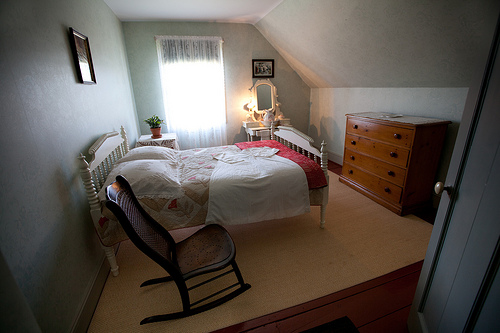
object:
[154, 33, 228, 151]
curtains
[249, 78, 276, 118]
mirror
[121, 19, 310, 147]
wall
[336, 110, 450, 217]
dresser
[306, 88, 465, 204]
wall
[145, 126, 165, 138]
flower pot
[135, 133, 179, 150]
table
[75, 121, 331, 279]
bed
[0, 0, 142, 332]
wall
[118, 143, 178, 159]
pillow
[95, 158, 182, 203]
pillow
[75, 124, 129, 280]
headboard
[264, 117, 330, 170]
footboard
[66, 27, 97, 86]
picture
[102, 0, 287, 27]
ceiling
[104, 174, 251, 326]
rocker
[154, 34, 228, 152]
window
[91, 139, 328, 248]
quilt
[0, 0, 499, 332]
bedroom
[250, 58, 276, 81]
picture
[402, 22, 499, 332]
door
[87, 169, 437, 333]
carpet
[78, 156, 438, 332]
floor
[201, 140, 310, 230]
nightgown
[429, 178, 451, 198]
doorknob